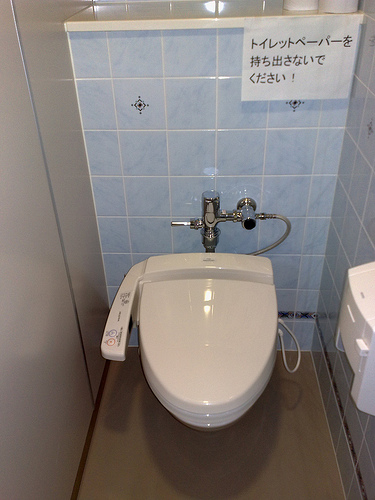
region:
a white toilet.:
[117, 234, 300, 436]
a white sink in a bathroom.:
[324, 239, 372, 422]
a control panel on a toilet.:
[94, 253, 145, 366]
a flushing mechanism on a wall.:
[162, 180, 307, 261]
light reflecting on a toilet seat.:
[195, 275, 223, 325]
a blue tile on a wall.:
[212, 133, 268, 182]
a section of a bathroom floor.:
[275, 409, 309, 484]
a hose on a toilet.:
[275, 314, 306, 372]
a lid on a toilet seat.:
[135, 252, 284, 410]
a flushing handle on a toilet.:
[167, 206, 203, 235]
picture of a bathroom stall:
[17, 0, 374, 491]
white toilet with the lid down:
[105, 248, 294, 420]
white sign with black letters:
[240, 16, 361, 101]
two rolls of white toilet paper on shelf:
[281, 0, 361, 21]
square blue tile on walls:
[103, 141, 366, 246]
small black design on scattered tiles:
[125, 84, 158, 126]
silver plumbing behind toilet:
[169, 198, 299, 254]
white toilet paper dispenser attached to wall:
[339, 258, 374, 417]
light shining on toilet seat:
[191, 281, 225, 323]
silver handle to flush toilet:
[166, 212, 201, 233]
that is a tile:
[107, 36, 165, 77]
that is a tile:
[129, 180, 170, 216]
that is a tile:
[167, 127, 212, 172]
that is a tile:
[263, 173, 308, 215]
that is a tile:
[306, 217, 323, 255]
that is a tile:
[214, 81, 262, 127]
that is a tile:
[96, 222, 130, 252]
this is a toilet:
[116, 255, 270, 418]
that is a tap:
[180, 177, 288, 255]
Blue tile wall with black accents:
[63, 3, 374, 495]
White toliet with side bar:
[98, 250, 302, 430]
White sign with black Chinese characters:
[242, 19, 359, 100]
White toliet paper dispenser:
[330, 261, 373, 422]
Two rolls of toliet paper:
[278, 2, 362, 14]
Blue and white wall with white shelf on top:
[64, 1, 367, 353]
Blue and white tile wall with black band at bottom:
[67, 32, 373, 494]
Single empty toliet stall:
[2, 45, 373, 499]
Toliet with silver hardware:
[96, 188, 296, 428]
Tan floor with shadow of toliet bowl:
[73, 342, 345, 498]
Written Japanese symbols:
[245, 21, 350, 100]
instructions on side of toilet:
[84, 284, 137, 352]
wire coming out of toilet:
[261, 320, 315, 374]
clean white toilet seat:
[151, 267, 272, 418]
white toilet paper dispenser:
[331, 279, 371, 408]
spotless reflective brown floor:
[104, 396, 314, 476]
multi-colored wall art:
[295, 295, 349, 415]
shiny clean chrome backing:
[173, 181, 294, 243]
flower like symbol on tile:
[115, 81, 162, 136]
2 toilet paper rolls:
[271, 3, 361, 15]